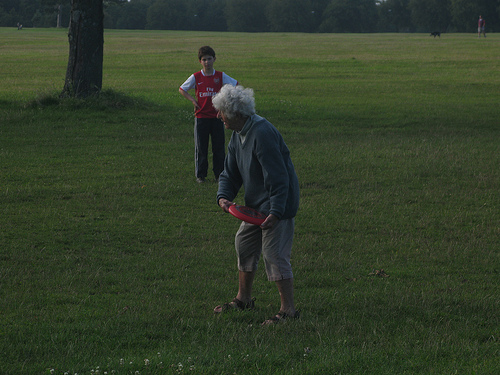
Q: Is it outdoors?
A: Yes, it is outdoors.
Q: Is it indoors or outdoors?
A: It is outdoors.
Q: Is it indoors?
A: No, it is outdoors.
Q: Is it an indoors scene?
A: No, it is outdoors.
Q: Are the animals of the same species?
A: Yes, all the animals are dogs.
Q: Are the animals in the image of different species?
A: No, all the animals are dogs.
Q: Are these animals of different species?
A: No, all the animals are dogs.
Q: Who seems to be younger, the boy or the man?
A: The boy is younger than the man.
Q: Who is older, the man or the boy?
A: The man is older than the boy.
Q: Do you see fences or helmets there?
A: No, there are no fences or helmets.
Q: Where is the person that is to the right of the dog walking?
A: The person is walking in the field.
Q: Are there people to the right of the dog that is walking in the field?
A: Yes, there is a person to the right of the dog.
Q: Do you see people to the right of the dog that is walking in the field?
A: Yes, there is a person to the right of the dog.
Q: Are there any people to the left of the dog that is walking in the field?
A: No, the person is to the right of the dog.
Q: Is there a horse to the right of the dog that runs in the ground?
A: No, there is a person to the right of the dog.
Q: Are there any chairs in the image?
A: No, there are no chairs.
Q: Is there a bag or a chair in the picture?
A: No, there are no chairs or bags.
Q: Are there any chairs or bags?
A: No, there are no chairs or bags.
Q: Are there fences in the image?
A: No, there are no fences.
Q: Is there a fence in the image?
A: No, there are no fences.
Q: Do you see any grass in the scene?
A: Yes, there is grass.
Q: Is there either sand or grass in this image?
A: Yes, there is grass.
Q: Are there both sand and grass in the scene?
A: No, there is grass but no sand.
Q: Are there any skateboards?
A: No, there are no skateboards.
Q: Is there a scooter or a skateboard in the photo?
A: No, there are no skateboards or scooters.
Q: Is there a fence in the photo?
A: No, there are no fences.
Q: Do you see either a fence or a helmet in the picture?
A: No, there are no fences or helmets.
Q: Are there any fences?
A: No, there are no fences.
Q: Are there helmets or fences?
A: No, there are no fences or helmets.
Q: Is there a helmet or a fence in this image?
A: No, there are no fences or helmets.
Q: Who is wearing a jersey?
A: The boy is wearing a jersey.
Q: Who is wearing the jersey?
A: The boy is wearing a jersey.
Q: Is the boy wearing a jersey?
A: Yes, the boy is wearing a jersey.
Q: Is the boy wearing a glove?
A: No, the boy is wearing a jersey.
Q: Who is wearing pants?
A: The boy is wearing pants.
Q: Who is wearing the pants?
A: The boy is wearing pants.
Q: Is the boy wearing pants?
A: Yes, the boy is wearing pants.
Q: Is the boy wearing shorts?
A: No, the boy is wearing pants.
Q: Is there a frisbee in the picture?
A: Yes, there is a frisbee.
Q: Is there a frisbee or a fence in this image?
A: Yes, there is a frisbee.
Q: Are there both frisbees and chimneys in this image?
A: No, there is a frisbee but no chimneys.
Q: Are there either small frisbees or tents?
A: Yes, there is a small frisbee.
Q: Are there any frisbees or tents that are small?
A: Yes, the frisbee is small.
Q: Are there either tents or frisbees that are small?
A: Yes, the frisbee is small.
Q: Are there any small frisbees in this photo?
A: Yes, there is a small frisbee.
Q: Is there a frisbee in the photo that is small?
A: Yes, there is a frisbee that is small.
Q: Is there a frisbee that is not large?
A: Yes, there is a small frisbee.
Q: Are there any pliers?
A: No, there are no pliers.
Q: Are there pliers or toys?
A: No, there are no pliers or toys.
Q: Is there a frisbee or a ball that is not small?
A: No, there is a frisbee but it is small.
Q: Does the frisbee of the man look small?
A: Yes, the frisbee is small.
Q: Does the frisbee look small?
A: Yes, the frisbee is small.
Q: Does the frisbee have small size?
A: Yes, the frisbee is small.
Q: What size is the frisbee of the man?
A: The frisbee is small.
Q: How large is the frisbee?
A: The frisbee is small.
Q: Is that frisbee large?
A: No, the frisbee is small.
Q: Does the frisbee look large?
A: No, the frisbee is small.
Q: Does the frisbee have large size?
A: No, the frisbee is small.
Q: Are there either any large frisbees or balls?
A: No, there is a frisbee but it is small.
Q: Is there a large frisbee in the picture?
A: No, there is a frisbee but it is small.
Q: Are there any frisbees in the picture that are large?
A: No, there is a frisbee but it is small.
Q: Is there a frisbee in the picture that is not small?
A: No, there is a frisbee but it is small.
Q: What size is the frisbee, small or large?
A: The frisbee is small.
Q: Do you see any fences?
A: No, there are no fences.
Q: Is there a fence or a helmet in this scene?
A: No, there are no fences or helmets.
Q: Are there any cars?
A: No, there are no cars.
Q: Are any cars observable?
A: No, there are no cars.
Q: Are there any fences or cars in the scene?
A: No, there are no cars or fences.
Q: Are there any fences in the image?
A: No, there are no fences.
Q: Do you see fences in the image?
A: No, there are no fences.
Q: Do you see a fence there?
A: No, there are no fences.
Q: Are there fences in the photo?
A: No, there are no fences.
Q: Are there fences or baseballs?
A: No, there are no fences or baseballs.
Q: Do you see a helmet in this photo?
A: No, there are no helmets.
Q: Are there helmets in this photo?
A: No, there are no helmets.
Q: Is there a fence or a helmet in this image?
A: No, there are no helmets or fences.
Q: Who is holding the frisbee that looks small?
A: The man is holding the frisbee.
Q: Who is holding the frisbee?
A: The man is holding the frisbee.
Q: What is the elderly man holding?
A: The man is holding the frisbee.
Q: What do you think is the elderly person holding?
A: The man is holding the frisbee.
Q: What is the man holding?
A: The man is holding the frisbee.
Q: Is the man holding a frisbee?
A: Yes, the man is holding a frisbee.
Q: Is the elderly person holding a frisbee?
A: Yes, the man is holding a frisbee.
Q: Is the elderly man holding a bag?
A: No, the man is holding a frisbee.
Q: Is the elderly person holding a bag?
A: No, the man is holding a frisbee.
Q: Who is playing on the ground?
A: The man is playing on the ground.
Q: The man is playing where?
A: The man is playing on the ground.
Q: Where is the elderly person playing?
A: The man is playing on the ground.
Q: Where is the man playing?
A: The man is playing on the ground.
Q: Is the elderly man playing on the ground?
A: Yes, the man is playing on the ground.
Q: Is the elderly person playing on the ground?
A: Yes, the man is playing on the ground.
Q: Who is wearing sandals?
A: The man is wearing sandals.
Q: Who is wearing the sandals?
A: The man is wearing sandals.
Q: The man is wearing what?
A: The man is wearing sandals.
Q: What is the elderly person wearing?
A: The man is wearing sandals.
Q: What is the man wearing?
A: The man is wearing sandals.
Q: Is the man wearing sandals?
A: Yes, the man is wearing sandals.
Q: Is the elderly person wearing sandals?
A: Yes, the man is wearing sandals.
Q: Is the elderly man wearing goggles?
A: No, the man is wearing sandals.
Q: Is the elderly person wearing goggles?
A: No, the man is wearing sandals.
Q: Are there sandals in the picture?
A: Yes, there are sandals.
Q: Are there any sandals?
A: Yes, there are sandals.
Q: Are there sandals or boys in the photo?
A: Yes, there are sandals.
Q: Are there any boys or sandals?
A: Yes, there are sandals.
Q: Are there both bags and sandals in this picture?
A: No, there are sandals but no bags.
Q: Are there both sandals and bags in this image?
A: No, there are sandals but no bags.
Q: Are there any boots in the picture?
A: No, there are no boots.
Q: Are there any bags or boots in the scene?
A: No, there are no boots or bags.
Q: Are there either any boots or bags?
A: No, there are no boots or bags.